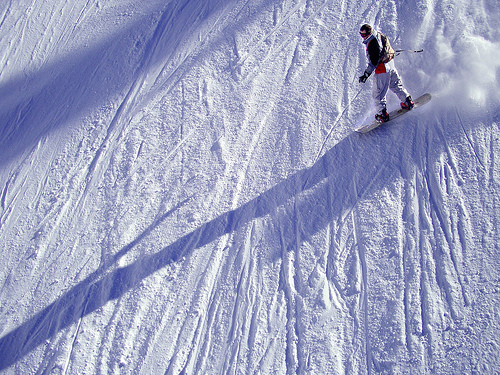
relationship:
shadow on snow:
[0, 108, 418, 374] [1, 2, 499, 375]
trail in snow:
[397, 118, 430, 373] [1, 2, 499, 375]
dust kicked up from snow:
[416, 34, 500, 125] [1, 2, 499, 375]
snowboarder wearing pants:
[358, 22, 414, 123] [374, 67, 413, 117]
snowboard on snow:
[354, 93, 432, 135] [1, 2, 499, 375]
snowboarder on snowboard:
[358, 22, 414, 123] [354, 93, 432, 135]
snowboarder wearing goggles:
[358, 22, 414, 123] [360, 32, 370, 39]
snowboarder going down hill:
[358, 22, 414, 123] [1, 1, 499, 374]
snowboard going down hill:
[354, 93, 432, 135] [1, 1, 499, 374]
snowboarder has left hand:
[358, 22, 414, 123] [358, 74, 369, 85]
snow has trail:
[1, 2, 499, 375] [397, 118, 430, 373]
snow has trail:
[1, 2, 499, 375] [319, 137, 376, 374]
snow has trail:
[1, 2, 499, 375] [273, 190, 309, 374]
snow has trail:
[1, 2, 499, 375] [220, 127, 289, 375]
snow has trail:
[1, 2, 499, 375] [0, 1, 35, 87]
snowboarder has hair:
[358, 22, 414, 123] [359, 23, 373, 35]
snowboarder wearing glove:
[358, 22, 414, 123] [358, 75, 366, 83]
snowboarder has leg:
[358, 22, 414, 123] [371, 78, 391, 111]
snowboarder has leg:
[358, 22, 414, 123] [388, 70, 411, 103]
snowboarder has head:
[358, 22, 414, 123] [359, 24, 373, 40]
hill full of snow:
[1, 1, 499, 374] [1, 2, 499, 375]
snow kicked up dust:
[1, 2, 499, 375] [416, 34, 500, 125]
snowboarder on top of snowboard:
[358, 22, 414, 123] [354, 93, 432, 135]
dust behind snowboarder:
[416, 34, 500, 125] [358, 22, 414, 123]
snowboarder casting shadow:
[358, 22, 414, 123] [0, 108, 418, 374]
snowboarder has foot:
[358, 22, 414, 123] [375, 112, 391, 123]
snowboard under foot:
[354, 93, 432, 135] [375, 112, 391, 123]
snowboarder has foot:
[358, 22, 414, 123] [399, 100, 415, 110]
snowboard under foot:
[354, 93, 432, 135] [399, 100, 415, 110]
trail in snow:
[355, 1, 435, 132] [1, 2, 499, 375]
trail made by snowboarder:
[355, 1, 435, 132] [358, 22, 414, 123]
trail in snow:
[0, 1, 35, 87] [1, 2, 499, 375]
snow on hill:
[1, 2, 499, 375] [1, 1, 499, 374]